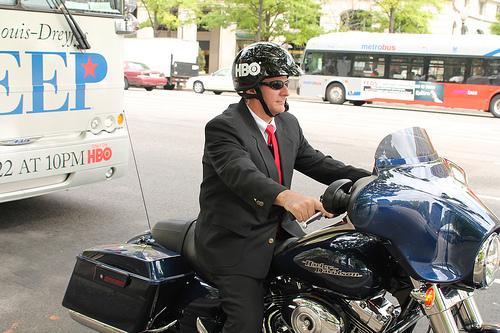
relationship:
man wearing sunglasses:
[190, 118, 348, 333] [270, 80, 294, 95]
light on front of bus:
[104, 165, 114, 183] [2, 99, 106, 150]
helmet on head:
[232, 38, 300, 92] [238, 76, 289, 115]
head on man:
[238, 76, 289, 115] [194, 43, 373, 330]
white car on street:
[185, 68, 236, 95] [124, 88, 240, 191]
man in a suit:
[194, 42, 372, 333] [195, 114, 367, 281]